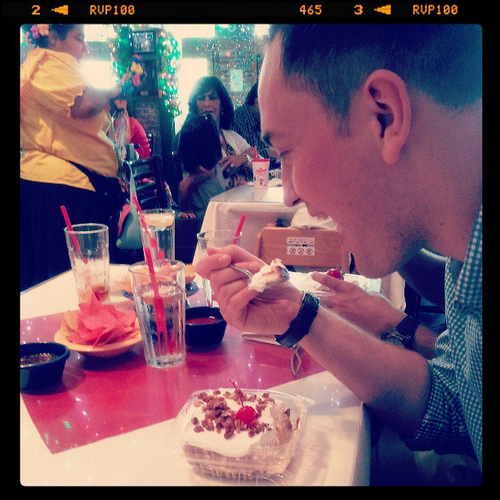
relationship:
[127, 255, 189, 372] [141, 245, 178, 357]
glass and straw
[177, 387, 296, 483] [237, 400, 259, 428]
dessert with cherry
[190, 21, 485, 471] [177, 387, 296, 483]
man eating dessert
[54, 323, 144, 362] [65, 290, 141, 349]
dish of chips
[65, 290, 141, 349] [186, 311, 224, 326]
chips with salsa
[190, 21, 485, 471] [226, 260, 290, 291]
man with fork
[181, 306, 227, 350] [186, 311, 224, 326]
bowl of salsa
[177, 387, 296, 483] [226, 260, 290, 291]
dessert on fork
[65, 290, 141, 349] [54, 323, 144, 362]
chips in dish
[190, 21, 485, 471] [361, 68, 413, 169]
man has an ear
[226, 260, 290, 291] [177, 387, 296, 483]
fork with dessert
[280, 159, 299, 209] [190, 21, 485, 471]
nose of man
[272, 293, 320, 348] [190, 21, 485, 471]
watch on man